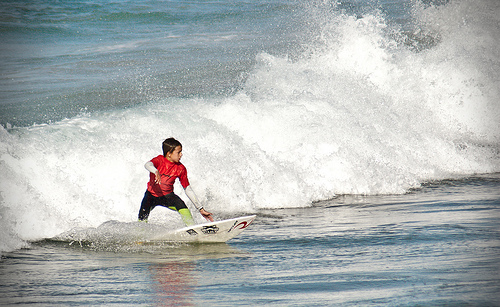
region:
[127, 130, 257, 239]
A young boy is surfing.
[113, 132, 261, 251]
A boy on a surfboard.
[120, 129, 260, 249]
The surfer is young.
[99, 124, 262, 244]
The boy is standing on a a surfboard.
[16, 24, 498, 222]
A wave on the ocean.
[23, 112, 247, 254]
The boy surfs in front of a wave.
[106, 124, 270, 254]
The boy is wearing a red shirt.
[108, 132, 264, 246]
The boy balances on a surfboard.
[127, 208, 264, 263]
The surfboard is mostly white in color.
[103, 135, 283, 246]
The boy is wearing black and green wet suit pants.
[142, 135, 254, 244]
A child riding a surfboard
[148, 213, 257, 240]
White surfboard in the water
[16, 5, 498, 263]
Water crashing as a wave crashes on itself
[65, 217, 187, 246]
Water splashing off of a surfboard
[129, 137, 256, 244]
Child surfing ahead of a wave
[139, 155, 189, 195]
Red surfer on a young surfer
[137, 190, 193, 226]
Black and green wet suit pants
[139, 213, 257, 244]
White surfboard being ridden in the water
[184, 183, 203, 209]
White sleeve of a wet suit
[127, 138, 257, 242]
Boy riding a surfboard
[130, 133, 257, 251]
Boy on a surfboard in the ocean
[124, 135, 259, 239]
Boy maneuvering a surfboard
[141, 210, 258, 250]
White surfboard with black and red design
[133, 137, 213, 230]
Boy wearing a red shirt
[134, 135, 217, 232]
Boy wearing black and green pants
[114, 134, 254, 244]
Boy riding an ocean wave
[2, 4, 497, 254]
White foamy ocean wave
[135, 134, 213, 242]
Boy wearing a wetsuit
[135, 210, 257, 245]
Surfboard in the ocean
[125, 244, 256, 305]
this is the water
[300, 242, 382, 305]
the water is blue in color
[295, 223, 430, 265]
the water has ripples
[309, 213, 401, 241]
the ripples are big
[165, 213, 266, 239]
this is a surfboard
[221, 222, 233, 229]
the surfboard is white in color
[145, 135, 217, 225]
this is a boy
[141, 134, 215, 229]
the boy is on the surfboard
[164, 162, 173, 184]
the swim suit is red in color